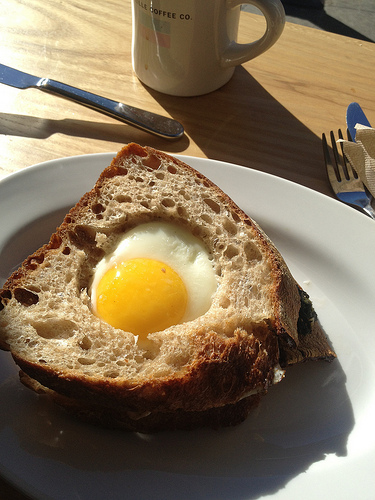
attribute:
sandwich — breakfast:
[0, 187, 302, 418]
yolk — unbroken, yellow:
[95, 254, 186, 337]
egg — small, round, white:
[89, 218, 219, 340]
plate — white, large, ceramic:
[2, 150, 374, 498]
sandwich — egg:
[1, 142, 303, 410]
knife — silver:
[1, 55, 193, 142]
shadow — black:
[4, 115, 190, 147]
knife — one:
[4, 61, 204, 138]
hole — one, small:
[32, 313, 79, 340]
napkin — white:
[338, 115, 375, 217]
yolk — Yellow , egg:
[85, 251, 189, 336]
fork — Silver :
[321, 121, 373, 217]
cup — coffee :
[127, 2, 285, 92]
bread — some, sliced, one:
[7, 137, 319, 436]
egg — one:
[82, 206, 217, 342]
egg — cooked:
[77, 207, 229, 344]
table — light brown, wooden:
[224, 72, 315, 164]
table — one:
[1, 38, 373, 186]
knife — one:
[3, 56, 187, 150]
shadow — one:
[2, 107, 185, 145]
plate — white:
[294, 425, 358, 493]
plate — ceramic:
[312, 433, 367, 495]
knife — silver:
[6, 92, 182, 137]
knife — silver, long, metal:
[1, 59, 185, 140]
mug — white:
[131, 2, 285, 96]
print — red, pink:
[133, 8, 173, 50]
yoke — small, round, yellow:
[89, 259, 193, 334]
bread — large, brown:
[1, 141, 340, 432]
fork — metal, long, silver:
[315, 126, 373, 216]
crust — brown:
[3, 138, 339, 423]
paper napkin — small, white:
[335, 122, 373, 203]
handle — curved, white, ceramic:
[224, 1, 290, 73]